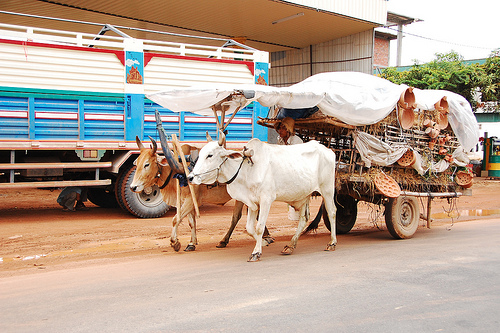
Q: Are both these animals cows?
A: Yes, all the animals are cows.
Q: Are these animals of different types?
A: No, all the animals are cows.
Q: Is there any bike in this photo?
A: No, there are no bikes.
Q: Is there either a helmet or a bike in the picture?
A: No, there are no bikes or helmets.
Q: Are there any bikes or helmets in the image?
A: No, there are no bikes or helmets.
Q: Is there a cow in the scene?
A: Yes, there is a cow.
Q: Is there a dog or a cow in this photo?
A: Yes, there is a cow.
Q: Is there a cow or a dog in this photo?
A: Yes, there is a cow.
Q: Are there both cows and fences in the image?
A: No, there is a cow but no fences.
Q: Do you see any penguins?
A: No, there are no penguins.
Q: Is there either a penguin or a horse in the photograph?
A: No, there are no penguins or horses.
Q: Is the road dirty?
A: Yes, the road is dirty.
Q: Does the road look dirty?
A: Yes, the road is dirty.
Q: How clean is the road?
A: The road is dirty.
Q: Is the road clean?
A: No, the road is dirty.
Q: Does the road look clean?
A: No, the road is dirty.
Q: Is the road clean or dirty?
A: The road is dirty.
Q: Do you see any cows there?
A: Yes, there is a cow.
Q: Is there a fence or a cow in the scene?
A: Yes, there is a cow.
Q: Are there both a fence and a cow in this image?
A: No, there is a cow but no fences.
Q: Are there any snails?
A: No, there are no snails.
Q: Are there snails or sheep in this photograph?
A: No, there are no snails or sheep.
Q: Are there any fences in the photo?
A: No, there are no fences.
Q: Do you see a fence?
A: No, there are no fences.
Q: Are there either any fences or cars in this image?
A: No, there are no fences or cars.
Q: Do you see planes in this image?
A: No, there are no planes.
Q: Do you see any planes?
A: No, there are no planes.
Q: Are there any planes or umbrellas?
A: No, there are no planes or umbrellas.